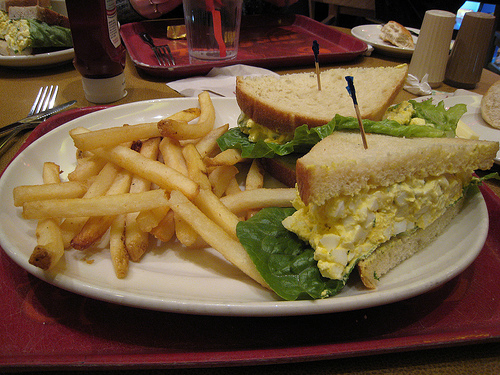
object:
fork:
[0, 84, 79, 158]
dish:
[0, 97, 491, 316]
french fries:
[13, 91, 303, 296]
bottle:
[65, 0, 128, 104]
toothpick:
[310, 41, 322, 90]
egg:
[280, 169, 470, 280]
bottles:
[407, 9, 498, 90]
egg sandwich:
[236, 62, 499, 290]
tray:
[1, 105, 500, 367]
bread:
[235, 63, 409, 139]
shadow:
[23, 262, 476, 351]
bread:
[296, 129, 499, 207]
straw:
[206, 10, 228, 59]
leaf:
[235, 206, 359, 299]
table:
[0, 0, 500, 375]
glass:
[190, 2, 232, 61]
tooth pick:
[343, 75, 370, 151]